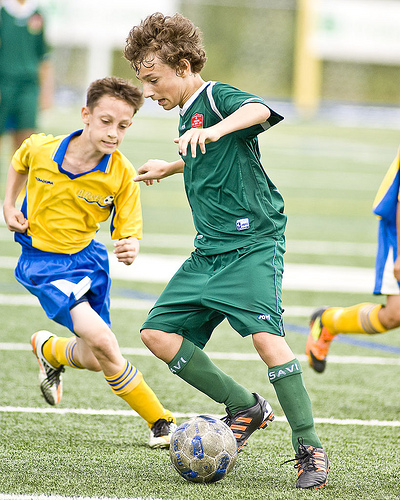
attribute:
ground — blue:
[319, 141, 333, 162]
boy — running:
[0, 76, 146, 448]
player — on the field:
[76, 25, 384, 418]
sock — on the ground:
[267, 357, 323, 454]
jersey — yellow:
[9, 128, 145, 254]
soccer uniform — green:
[138, 81, 288, 350]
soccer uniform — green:
[10, 128, 144, 256]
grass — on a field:
[322, 373, 388, 473]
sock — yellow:
[96, 367, 163, 448]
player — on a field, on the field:
[121, 11, 331, 489]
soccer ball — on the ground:
[157, 399, 254, 492]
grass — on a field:
[12, 400, 102, 468]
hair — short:
[82, 67, 137, 148]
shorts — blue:
[7, 244, 122, 318]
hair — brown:
[151, 24, 213, 61]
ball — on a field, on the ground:
[170, 415, 237, 482]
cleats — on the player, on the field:
[31, 329, 64, 405]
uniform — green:
[133, 88, 342, 438]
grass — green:
[2, 297, 398, 496]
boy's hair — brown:
[83, 76, 141, 121]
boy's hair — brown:
[128, 12, 204, 69]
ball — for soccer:
[149, 398, 265, 473]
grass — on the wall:
[1, 122, 398, 498]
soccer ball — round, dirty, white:
[169, 412, 235, 483]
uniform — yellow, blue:
[13, 130, 141, 331]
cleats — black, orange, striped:
[225, 396, 274, 454]